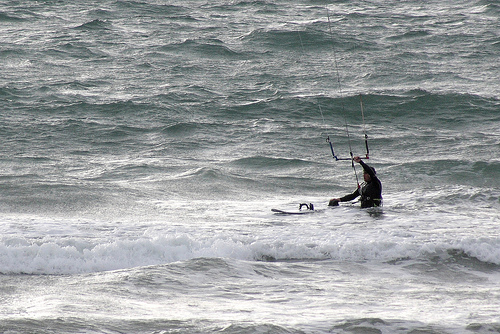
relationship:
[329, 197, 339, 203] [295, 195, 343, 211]
hand holding handle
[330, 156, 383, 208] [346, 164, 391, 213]
person wearing wetsuit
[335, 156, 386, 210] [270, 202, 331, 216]
person next to surfboard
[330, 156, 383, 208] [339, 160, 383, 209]
person wearing wetsuit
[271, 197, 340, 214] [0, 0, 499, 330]
board floating on water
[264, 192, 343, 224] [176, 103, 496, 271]
board floating in water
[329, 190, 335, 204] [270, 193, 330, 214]
hand holding board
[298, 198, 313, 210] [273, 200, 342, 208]
foot strap of board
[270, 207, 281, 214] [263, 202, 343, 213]
edge of board